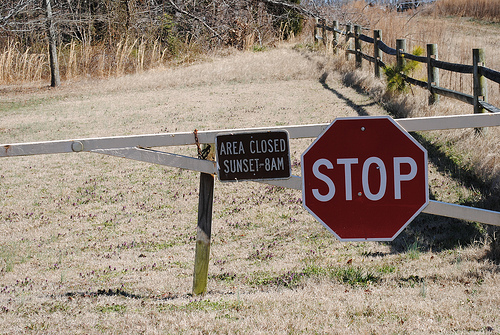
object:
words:
[361, 156, 387, 202]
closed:
[250, 138, 286, 154]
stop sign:
[300, 115, 431, 242]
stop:
[312, 156, 420, 205]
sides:
[424, 151, 430, 204]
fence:
[312, 17, 499, 132]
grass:
[347, 69, 382, 95]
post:
[193, 144, 217, 295]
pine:
[1, 0, 102, 86]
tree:
[167, 0, 232, 47]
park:
[0, 0, 498, 334]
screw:
[249, 135, 254, 139]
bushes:
[479, 1, 499, 16]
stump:
[232, 33, 254, 53]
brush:
[0, 33, 20, 82]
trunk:
[41, 0, 62, 88]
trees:
[109, 0, 155, 30]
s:
[312, 158, 336, 203]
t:
[335, 157, 359, 201]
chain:
[191, 129, 212, 160]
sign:
[214, 129, 293, 183]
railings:
[0, 112, 500, 294]